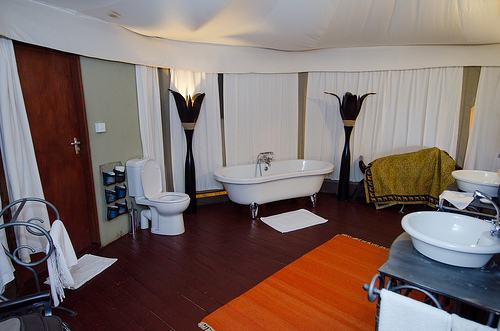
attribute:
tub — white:
[212, 148, 333, 219]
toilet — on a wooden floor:
[125, 155, 192, 235]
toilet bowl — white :
[137, 185, 190, 236]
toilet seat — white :
[151, 189, 190, 205]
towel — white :
[31, 215, 95, 312]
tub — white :
[223, 141, 380, 216]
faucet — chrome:
[464, 189, 499, 236]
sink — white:
[451, 162, 498, 190]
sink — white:
[402, 209, 499, 266]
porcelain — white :
[122, 156, 148, 181]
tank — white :
[132, 157, 186, 201]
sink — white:
[386, 197, 466, 257]